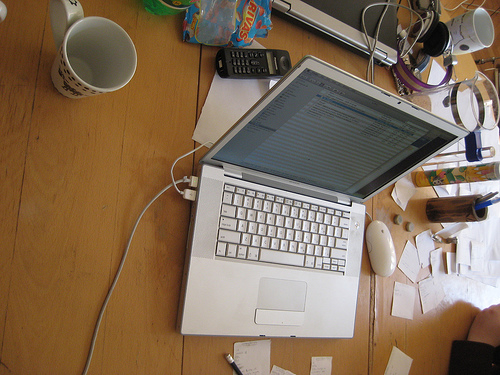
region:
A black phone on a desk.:
[215, 42, 290, 79]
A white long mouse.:
[368, 216, 396, 276]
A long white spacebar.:
[257, 244, 306, 265]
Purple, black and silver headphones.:
[394, 7, 454, 96]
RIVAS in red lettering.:
[239, 2, 256, 42]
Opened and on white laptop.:
[177, 57, 469, 337]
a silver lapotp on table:
[187, 80, 321, 356]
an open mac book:
[229, 94, 367, 369]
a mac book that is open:
[203, 41, 350, 322]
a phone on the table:
[204, 28, 296, 88]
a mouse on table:
[351, 208, 419, 288]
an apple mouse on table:
[355, 208, 455, 324]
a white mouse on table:
[351, 213, 417, 303]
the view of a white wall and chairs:
[282, 283, 304, 309]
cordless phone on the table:
[213, 49, 289, 76]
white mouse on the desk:
[369, 225, 392, 270]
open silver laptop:
[188, 58, 466, 348]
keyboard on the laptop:
[217, 184, 345, 275]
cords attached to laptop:
[73, 141, 211, 373]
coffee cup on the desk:
[45, 2, 136, 98]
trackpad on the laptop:
[253, 278, 305, 311]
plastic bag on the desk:
[183, 2, 269, 49]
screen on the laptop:
[203, 67, 449, 192]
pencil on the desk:
[223, 351, 242, 371]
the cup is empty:
[58, 8, 143, 122]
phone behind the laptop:
[203, 14, 439, 291]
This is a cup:
[34, 7, 137, 108]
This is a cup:
[421, 5, 498, 45]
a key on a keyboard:
[214, 241, 224, 258]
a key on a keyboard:
[226, 242, 233, 259]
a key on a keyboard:
[237, 246, 246, 263]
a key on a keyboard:
[246, 247, 258, 262]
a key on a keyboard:
[262, 249, 307, 270]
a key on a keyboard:
[220, 229, 243, 242]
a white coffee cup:
[30, 5, 142, 115]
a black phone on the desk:
[192, 32, 298, 97]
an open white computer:
[179, 33, 466, 373]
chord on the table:
[76, 144, 179, 373]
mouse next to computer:
[362, 214, 404, 290]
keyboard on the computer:
[219, 169, 356, 298]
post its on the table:
[383, 216, 462, 333]